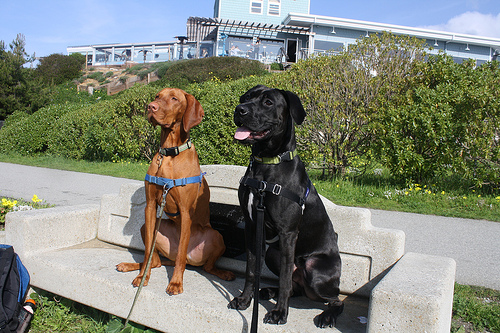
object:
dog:
[113, 84, 239, 297]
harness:
[143, 171, 207, 189]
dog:
[224, 78, 342, 330]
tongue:
[234, 127, 251, 140]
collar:
[155, 138, 195, 158]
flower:
[31, 194, 43, 203]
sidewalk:
[1, 161, 106, 213]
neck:
[154, 127, 192, 160]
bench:
[1, 158, 457, 333]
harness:
[237, 176, 315, 208]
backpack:
[0, 241, 34, 333]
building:
[63, 0, 498, 69]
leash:
[103, 215, 163, 332]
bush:
[375, 62, 495, 183]